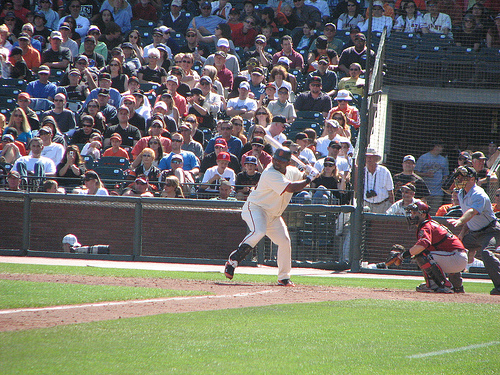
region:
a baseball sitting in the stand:
[134, 146, 160, 180]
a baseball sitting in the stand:
[164, 132, 203, 172]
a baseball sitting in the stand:
[102, 106, 142, 142]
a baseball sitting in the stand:
[67, 107, 101, 145]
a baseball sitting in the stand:
[91, 74, 118, 103]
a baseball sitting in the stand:
[160, 74, 187, 110]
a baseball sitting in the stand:
[225, 79, 260, 113]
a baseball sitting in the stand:
[267, 84, 296, 120]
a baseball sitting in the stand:
[298, 74, 338, 110]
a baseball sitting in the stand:
[265, 67, 297, 94]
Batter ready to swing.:
[223, 132, 318, 294]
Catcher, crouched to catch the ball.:
[362, 194, 472, 295]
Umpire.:
[447, 162, 499, 296]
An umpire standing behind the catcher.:
[376, 159, 498, 298]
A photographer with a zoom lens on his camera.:
[59, 231, 113, 258]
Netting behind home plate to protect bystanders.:
[353, 0, 498, 277]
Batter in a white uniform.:
[220, 133, 322, 293]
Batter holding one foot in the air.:
[220, 137, 320, 297]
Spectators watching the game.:
[2, 29, 499, 221]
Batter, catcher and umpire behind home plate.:
[223, 134, 496, 299]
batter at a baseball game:
[225, 136, 337, 290]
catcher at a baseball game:
[388, 200, 470, 303]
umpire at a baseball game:
[453, 152, 498, 305]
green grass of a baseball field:
[229, 317, 375, 365]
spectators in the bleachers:
[19, 16, 251, 191]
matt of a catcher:
[380, 230, 411, 272]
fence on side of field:
[11, 164, 226, 283]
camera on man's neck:
[363, 179, 378, 202]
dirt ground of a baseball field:
[298, 279, 403, 302]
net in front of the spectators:
[386, 23, 483, 135]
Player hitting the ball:
[212, 138, 319, 287]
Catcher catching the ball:
[395, 187, 468, 299]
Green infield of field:
[227, 321, 360, 370]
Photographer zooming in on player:
[57, 228, 116, 253]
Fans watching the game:
[96, 28, 268, 148]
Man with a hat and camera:
[366, 146, 394, 212]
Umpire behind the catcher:
[450, 164, 495, 219]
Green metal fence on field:
[79, 191, 191, 233]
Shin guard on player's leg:
[226, 233, 255, 278]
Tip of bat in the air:
[262, 133, 284, 147]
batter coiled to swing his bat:
[223, 133, 320, 289]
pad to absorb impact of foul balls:
[232, 242, 252, 264]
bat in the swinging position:
[262, 133, 320, 178]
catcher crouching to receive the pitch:
[388, 198, 467, 290]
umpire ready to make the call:
[434, 164, 499, 296]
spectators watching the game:
[0, 2, 498, 204]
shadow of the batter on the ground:
[209, 279, 278, 287]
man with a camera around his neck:
[362, 148, 394, 212]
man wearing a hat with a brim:
[362, 150, 394, 213]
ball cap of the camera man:
[61, 235, 81, 251]